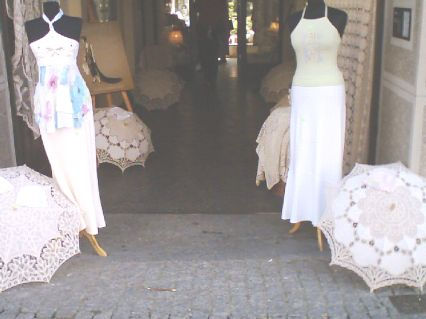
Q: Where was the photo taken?
A: At a store.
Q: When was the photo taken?
A: Day time.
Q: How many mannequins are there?
A: Two.